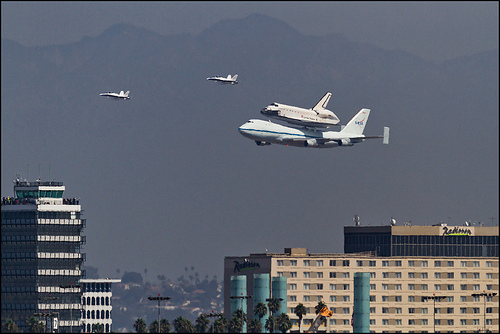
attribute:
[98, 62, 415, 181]
jets — military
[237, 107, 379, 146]
plane — white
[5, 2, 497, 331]
sky — blue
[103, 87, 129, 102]
plane — on the air, fighter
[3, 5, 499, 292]
sky — blue, hazy blue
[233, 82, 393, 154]
plane — white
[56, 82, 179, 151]
plane — white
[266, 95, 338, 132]
jets — military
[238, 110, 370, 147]
jets — military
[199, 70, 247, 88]
jets — military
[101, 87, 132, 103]
jets — military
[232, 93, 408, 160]
airplane — owned by NASA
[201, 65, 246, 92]
plane — fighter, on the air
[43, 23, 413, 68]
sky — blue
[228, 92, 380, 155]
shuttle — United State space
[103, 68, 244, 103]
planes — two additional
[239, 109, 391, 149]
plane — flying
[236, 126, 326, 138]
stripe — blue